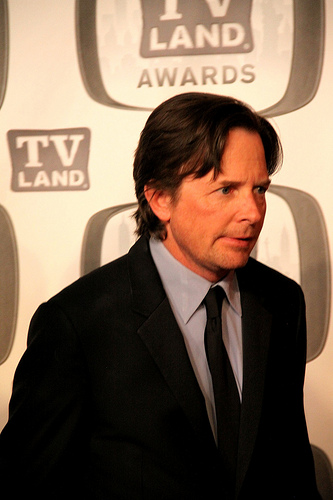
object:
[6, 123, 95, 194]
tv land award logo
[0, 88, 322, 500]
man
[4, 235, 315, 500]
suit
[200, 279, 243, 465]
tie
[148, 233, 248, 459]
shirt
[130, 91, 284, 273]
head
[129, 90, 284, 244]
hair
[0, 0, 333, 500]
wall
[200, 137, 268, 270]
face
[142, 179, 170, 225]
ear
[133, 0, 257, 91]
logo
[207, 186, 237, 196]
eye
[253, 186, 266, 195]
eye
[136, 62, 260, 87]
awards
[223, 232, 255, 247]
mouth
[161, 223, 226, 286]
neck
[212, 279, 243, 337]
shadow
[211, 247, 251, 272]
chin stubble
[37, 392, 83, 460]
crease mark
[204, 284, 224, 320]
knot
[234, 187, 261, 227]
nose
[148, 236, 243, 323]
collar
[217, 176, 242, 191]
eyebrow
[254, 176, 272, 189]
eyebrow